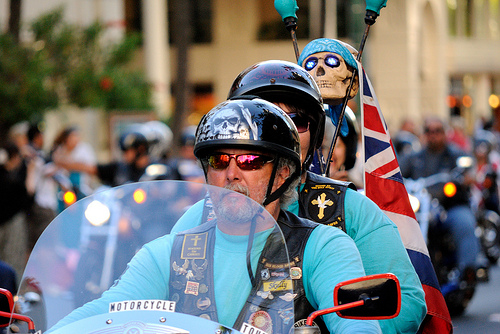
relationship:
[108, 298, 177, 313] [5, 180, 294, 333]
word attached to windshield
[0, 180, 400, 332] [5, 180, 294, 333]
motorcycle has windshield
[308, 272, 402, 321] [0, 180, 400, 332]
left side mirror attached to motorcycle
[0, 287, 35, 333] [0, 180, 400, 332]
right side mirror attached to motorcycle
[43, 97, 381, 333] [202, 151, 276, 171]
man wearing sunglasses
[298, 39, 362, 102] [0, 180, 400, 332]
skull behind motorcycle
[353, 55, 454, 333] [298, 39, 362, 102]
flag near skull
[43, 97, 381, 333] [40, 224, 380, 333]
man wearing shirt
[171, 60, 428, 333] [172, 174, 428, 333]
woman wearing shirt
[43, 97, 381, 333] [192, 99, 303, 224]
man wearing helmet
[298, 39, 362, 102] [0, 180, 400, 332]
skull attached to back of motorcycle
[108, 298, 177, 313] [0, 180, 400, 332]
word attached to motorcycle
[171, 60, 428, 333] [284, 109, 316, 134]
woman wearing sunglasses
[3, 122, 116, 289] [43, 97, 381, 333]
people behind man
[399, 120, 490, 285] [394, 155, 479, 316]
person riding motorcycle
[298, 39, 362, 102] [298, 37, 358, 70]
skull wearing bandana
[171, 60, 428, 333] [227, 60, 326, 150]
woman wearing helmet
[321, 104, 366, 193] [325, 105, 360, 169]
person wearing helmet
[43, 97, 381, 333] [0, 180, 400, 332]
man riding motorcycle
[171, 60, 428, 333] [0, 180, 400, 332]
woman riding motorcycle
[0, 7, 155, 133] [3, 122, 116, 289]
tree behind people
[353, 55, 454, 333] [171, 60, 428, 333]
flag behind woman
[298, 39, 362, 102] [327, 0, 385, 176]
skull next to pole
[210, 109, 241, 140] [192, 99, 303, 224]
skull printed on helmet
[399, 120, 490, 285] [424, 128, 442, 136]
person wearing sunglasses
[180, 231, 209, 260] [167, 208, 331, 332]
patch sewn on vest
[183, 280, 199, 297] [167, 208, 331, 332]
patch sewn on vest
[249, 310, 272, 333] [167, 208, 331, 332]
patch sewn on vest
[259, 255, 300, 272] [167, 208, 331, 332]
patch sewn on vest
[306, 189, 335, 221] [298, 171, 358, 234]
patch sewn on vest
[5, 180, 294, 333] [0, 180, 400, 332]
windshield attached to motorcycle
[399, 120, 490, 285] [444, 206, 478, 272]
person wearing pants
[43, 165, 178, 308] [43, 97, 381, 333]
motorcycle behind man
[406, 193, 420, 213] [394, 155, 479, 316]
headlight attached to motorcycle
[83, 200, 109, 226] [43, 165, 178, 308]
headlight attached to motorcycle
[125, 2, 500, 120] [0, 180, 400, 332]
building behind motorcycle